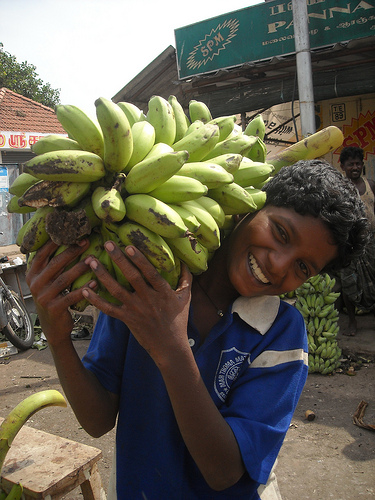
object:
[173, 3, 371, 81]
sign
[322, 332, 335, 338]
bananas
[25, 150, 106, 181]
bananas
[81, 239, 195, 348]
hands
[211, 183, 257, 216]
bananas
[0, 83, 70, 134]
roof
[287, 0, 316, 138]
pole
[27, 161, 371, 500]
boy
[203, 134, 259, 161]
banana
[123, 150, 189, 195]
banana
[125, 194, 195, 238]
banana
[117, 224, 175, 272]
banana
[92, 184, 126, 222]
banana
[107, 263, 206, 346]
shoulder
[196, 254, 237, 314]
neck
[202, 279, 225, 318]
necklace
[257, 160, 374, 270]
curly hair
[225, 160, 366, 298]
head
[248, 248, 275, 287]
smile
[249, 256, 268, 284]
teeth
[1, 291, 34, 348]
wheel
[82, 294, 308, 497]
shirt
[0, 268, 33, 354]
motorcycle tire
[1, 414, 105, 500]
stool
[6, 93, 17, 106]
tile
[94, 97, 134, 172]
banana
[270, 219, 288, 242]
eyes